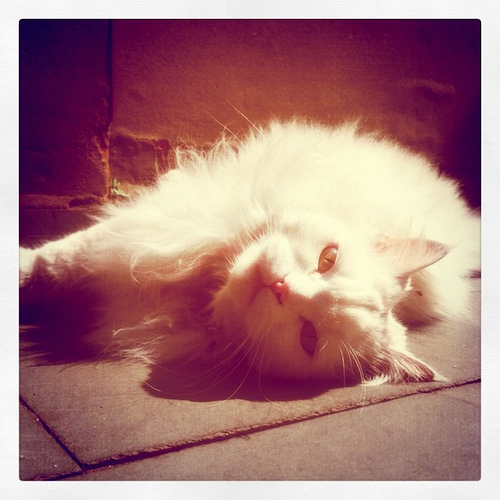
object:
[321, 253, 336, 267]
pupil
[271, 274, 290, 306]
nose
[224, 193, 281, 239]
whiskers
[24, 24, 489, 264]
wall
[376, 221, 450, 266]
hairs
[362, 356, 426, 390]
hairs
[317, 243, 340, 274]
eye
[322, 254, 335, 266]
slit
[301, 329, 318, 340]
slit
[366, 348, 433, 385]
ear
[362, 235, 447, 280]
ear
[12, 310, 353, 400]
shadow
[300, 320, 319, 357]
eyes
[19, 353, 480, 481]
ground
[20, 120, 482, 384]
cat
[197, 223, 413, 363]
camera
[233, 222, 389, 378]
face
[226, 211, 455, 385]
head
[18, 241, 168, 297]
legs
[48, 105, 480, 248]
fur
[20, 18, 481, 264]
background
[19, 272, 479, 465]
tile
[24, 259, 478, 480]
pavement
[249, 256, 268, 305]
mouth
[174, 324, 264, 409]
whiskers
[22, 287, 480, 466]
rug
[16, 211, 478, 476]
floor